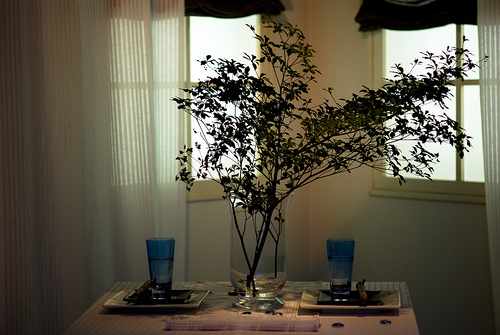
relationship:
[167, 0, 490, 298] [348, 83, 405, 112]
plant has leaves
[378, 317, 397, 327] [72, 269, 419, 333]
leaf on table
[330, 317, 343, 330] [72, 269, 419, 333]
leaf on table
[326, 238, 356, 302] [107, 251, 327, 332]
clear glass on table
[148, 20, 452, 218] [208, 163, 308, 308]
limbs in vase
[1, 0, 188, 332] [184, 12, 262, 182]
curtain in window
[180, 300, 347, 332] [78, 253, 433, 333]
napkins on table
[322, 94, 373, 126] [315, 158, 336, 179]
leaves on limb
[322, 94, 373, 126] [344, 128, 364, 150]
leaves on limb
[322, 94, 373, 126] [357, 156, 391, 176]
leaves on limb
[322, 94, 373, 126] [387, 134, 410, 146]
leaves on limb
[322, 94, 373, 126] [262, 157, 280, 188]
leaves on limb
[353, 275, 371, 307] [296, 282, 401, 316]
chop sticks on plate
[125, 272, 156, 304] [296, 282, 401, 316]
chop sticks on plate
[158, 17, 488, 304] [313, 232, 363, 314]
plant in vase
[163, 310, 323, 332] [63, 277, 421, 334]
placemat on table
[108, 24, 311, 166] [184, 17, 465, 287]
window to left of plant